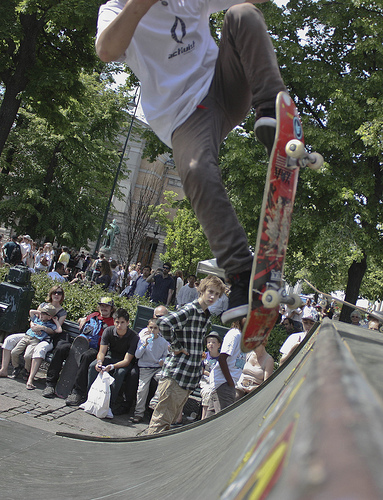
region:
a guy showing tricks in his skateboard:
[91, 2, 306, 347]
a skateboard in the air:
[198, 106, 365, 383]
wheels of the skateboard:
[287, 140, 325, 181]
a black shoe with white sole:
[208, 252, 258, 339]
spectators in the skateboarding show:
[4, 211, 199, 412]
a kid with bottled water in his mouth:
[133, 311, 168, 401]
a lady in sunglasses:
[1, 274, 66, 395]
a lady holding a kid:
[1, 275, 66, 395]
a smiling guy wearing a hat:
[90, 289, 114, 326]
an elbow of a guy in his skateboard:
[84, 7, 131, 77]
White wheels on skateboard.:
[291, 120, 328, 213]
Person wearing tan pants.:
[135, 369, 214, 422]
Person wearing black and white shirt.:
[180, 350, 210, 398]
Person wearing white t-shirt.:
[215, 348, 253, 393]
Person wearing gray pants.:
[209, 384, 242, 437]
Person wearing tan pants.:
[129, 373, 166, 436]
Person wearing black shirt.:
[111, 349, 132, 365]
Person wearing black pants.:
[45, 354, 73, 376]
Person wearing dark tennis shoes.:
[36, 377, 98, 423]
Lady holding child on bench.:
[13, 308, 63, 368]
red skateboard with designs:
[247, 85, 296, 342]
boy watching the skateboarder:
[150, 258, 223, 417]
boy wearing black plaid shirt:
[163, 248, 214, 416]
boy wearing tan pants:
[148, 256, 219, 417]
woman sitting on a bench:
[13, 277, 63, 377]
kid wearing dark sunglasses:
[14, 299, 51, 377]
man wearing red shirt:
[40, 288, 113, 400]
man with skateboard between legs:
[43, 286, 110, 404]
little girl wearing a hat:
[200, 328, 222, 397]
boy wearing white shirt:
[136, 316, 171, 422]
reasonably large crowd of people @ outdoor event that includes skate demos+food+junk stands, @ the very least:
[0, 222, 381, 440]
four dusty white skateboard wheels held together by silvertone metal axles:
[256, 129, 329, 322]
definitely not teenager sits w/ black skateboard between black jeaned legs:
[35, 291, 121, 411]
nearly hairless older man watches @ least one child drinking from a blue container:
[123, 303, 177, 429]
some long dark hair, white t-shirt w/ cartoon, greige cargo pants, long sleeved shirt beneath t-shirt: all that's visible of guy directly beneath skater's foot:
[202, 312, 258, 421]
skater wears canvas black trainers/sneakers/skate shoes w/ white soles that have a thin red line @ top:
[212, 101, 287, 329]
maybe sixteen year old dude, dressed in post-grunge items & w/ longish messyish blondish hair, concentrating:
[143, 265, 232, 440]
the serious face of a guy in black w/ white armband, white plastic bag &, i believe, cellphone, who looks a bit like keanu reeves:
[78, 299, 145, 425]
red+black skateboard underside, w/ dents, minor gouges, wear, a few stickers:
[233, 89, 315, 363]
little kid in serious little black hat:
[195, 326, 224, 420]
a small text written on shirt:
[163, 22, 212, 88]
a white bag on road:
[86, 361, 123, 428]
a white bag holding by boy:
[71, 345, 136, 447]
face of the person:
[191, 268, 244, 317]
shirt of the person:
[160, 291, 219, 411]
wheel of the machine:
[251, 275, 312, 355]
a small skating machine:
[245, 77, 337, 481]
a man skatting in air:
[135, 8, 316, 324]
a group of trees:
[33, 129, 374, 331]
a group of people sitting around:
[18, 218, 367, 423]